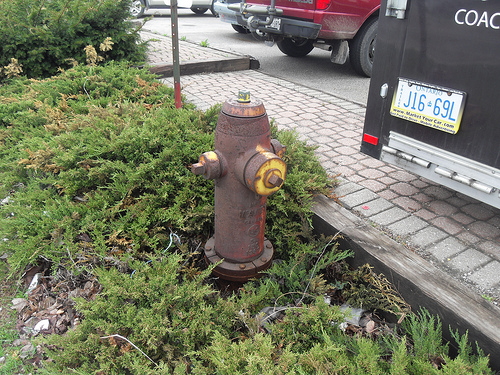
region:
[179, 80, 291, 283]
The fire hydrant is faded.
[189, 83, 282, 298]
The fire hydrant is rusted.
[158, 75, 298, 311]
The fire hydrant is on the ground.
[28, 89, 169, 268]
The shrubs are green.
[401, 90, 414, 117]
The letter is blue.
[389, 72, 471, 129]
The license plate is white.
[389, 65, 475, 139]
The license plate is rectangular.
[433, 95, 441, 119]
The number is blue.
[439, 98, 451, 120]
The number is blue.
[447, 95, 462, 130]
The letter is blue.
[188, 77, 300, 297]
the fire hydrant in the bushes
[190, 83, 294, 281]
the rusted fire hydrant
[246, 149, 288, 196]
the yellow cap on the hydrant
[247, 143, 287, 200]
the yellow paint rusting on the hydrant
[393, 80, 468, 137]
the white plate on the trailer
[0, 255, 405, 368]
the bushes by the base of the hydrant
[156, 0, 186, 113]
the pole in the bushes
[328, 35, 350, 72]
the flap of the truck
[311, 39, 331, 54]
the exhaust under the truck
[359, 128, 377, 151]
the red brake light on the trailer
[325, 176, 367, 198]
The brick is gray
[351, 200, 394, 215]
The brick is gray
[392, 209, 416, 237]
The brick is gray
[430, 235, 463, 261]
The brick is gray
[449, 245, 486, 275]
The brick is gray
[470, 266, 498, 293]
The brick is gray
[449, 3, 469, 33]
The letter is white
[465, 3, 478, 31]
The letter is white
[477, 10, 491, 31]
The letter is white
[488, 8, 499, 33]
The letter is white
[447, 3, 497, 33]
white letters on car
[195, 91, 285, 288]
fire hydrant behind the wood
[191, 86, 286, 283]
fire hydrant is rusty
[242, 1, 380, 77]
the truck is red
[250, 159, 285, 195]
yellow part on hydrant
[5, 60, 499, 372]
bushes around the hydrant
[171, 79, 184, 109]
bottom of post is red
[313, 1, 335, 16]
red tail light on truck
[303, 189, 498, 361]
wooden log in front of hydrant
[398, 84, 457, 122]
blue letters on plate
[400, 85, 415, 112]
The letter is blue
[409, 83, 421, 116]
The number is blue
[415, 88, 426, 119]
The number is blue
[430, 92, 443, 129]
The number is blue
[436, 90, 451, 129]
The number is blue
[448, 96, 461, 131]
The letter is blue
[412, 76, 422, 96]
The letter is blue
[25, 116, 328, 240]
The bush is green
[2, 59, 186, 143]
The bush is green